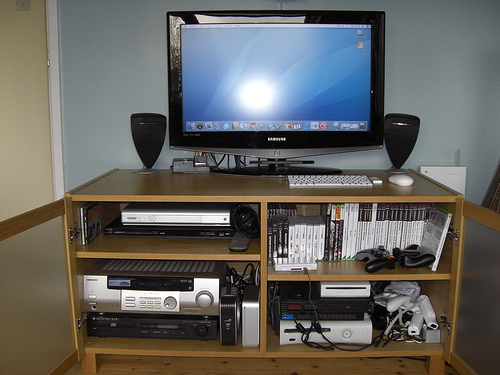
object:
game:
[267, 202, 452, 273]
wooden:
[128, 175, 207, 198]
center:
[67, 196, 463, 372]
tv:
[165, 9, 385, 158]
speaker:
[130, 113, 167, 175]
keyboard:
[287, 175, 373, 188]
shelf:
[264, 200, 453, 277]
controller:
[356, 247, 396, 273]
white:
[273, 257, 317, 271]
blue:
[82, 38, 141, 87]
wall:
[398, 11, 479, 107]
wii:
[419, 295, 436, 332]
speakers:
[383, 113, 420, 174]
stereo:
[82, 259, 226, 319]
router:
[218, 288, 240, 346]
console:
[279, 313, 372, 345]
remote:
[229, 232, 252, 252]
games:
[320, 202, 358, 262]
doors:
[0, 196, 82, 373]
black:
[356, 244, 436, 273]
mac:
[242, 285, 261, 349]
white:
[388, 174, 415, 187]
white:
[369, 176, 384, 184]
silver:
[121, 203, 231, 227]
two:
[406, 295, 439, 336]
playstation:
[278, 297, 374, 320]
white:
[319, 282, 371, 299]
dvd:
[80, 203, 102, 245]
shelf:
[67, 201, 264, 255]